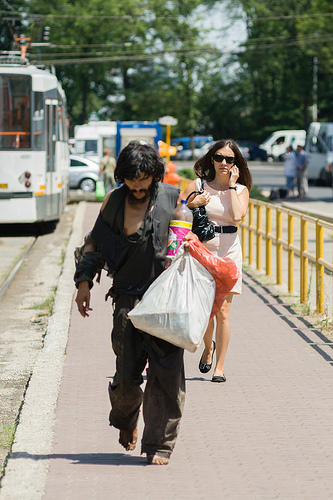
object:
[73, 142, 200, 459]
man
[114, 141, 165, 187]
hair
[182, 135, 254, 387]
woman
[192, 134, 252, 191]
hair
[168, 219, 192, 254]
label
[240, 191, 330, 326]
railing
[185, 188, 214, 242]
purse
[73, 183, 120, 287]
sleeve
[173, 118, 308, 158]
cars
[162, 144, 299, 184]
street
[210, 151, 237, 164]
sunglasses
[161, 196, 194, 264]
bottle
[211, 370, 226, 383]
dress shoes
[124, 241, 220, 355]
bag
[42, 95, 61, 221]
metal doors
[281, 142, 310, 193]
two men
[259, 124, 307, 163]
van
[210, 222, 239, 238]
belt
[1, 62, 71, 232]
bus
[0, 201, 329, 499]
sidewalk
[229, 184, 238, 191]
wristwatch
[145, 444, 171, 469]
man's feet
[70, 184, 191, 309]
shirt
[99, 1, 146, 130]
trees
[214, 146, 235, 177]
woman's face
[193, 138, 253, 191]
woman's head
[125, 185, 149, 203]
beard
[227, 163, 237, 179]
cell phone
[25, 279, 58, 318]
weeds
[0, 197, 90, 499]
curb